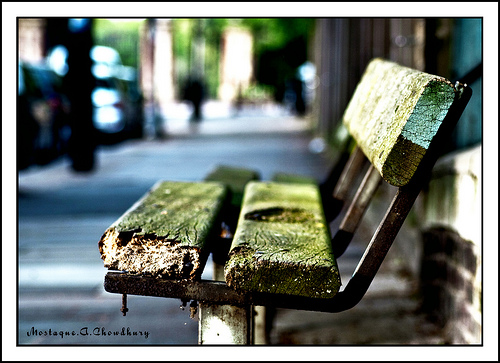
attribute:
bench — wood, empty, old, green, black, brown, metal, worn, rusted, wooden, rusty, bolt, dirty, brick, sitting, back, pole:
[83, 43, 466, 310]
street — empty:
[115, 72, 359, 180]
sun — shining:
[130, 53, 310, 133]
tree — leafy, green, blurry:
[246, 27, 297, 62]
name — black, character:
[11, 301, 156, 348]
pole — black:
[34, 26, 116, 207]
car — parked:
[27, 32, 163, 140]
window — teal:
[356, 32, 478, 101]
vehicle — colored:
[46, 38, 183, 166]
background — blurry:
[82, 29, 291, 160]